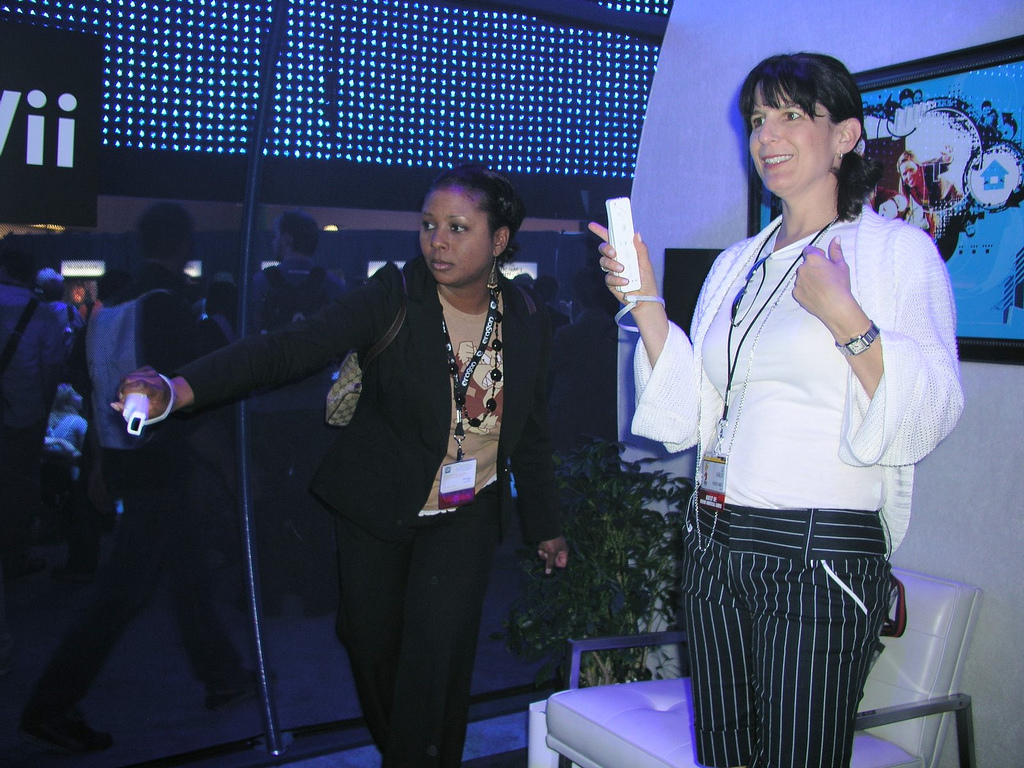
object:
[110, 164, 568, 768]
girl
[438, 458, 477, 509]
id card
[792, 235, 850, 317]
hand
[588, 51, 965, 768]
woman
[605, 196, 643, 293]
wii remote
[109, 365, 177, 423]
hand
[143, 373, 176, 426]
band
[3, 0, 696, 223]
wall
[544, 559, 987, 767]
chair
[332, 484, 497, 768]
pants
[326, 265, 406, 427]
purse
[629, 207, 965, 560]
shirt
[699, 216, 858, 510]
lanyard